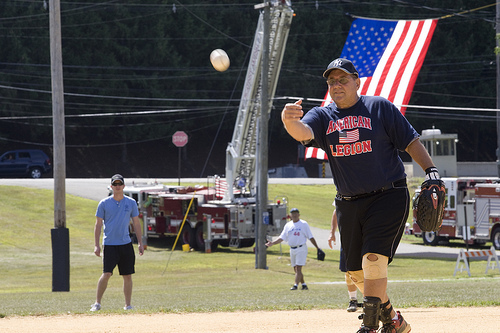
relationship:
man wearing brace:
[280, 58, 449, 333] [362, 253, 389, 280]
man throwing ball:
[280, 58, 449, 333] [204, 42, 234, 73]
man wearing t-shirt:
[265, 205, 328, 287] [276, 217, 316, 247]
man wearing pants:
[265, 205, 328, 287] [277, 242, 314, 267]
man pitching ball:
[261, 41, 470, 281] [209, 43, 226, 70]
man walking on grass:
[264, 208, 326, 290] [7, 174, 489, 314]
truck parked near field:
[403, 174, 497, 264] [7, 193, 496, 307]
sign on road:
[168, 128, 188, 148] [10, 172, 334, 187]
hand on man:
[276, 95, 308, 129] [280, 58, 449, 333]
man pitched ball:
[280, 58, 449, 333] [208, 16, 238, 79]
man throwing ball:
[280, 58, 449, 333] [209, 47, 229, 71]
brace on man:
[362, 252, 387, 285] [280, 58, 449, 333]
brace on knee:
[362, 252, 387, 285] [346, 277, 360, 286]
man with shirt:
[90, 175, 145, 315] [93, 195, 143, 248]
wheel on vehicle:
[488, 223, 498, 246] [411, 168, 498, 247]